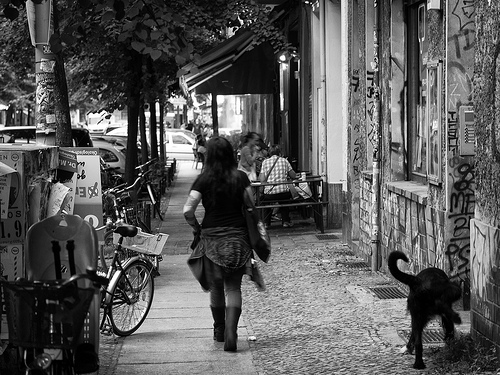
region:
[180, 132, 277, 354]
A woman walking down a street.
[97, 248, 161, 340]
a bike tire on a bike.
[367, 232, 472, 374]
a dog near a wall.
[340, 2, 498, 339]
a wall for a building.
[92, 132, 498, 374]
a sidewalk near a building.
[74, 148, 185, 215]
a set of handle bars on a bike.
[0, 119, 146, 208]
a parking lot full of cars.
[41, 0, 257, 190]
a tree with lots of green leaves.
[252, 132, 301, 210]
a shirt with lines.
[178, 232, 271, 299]
a sweater around a waist.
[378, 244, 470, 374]
dog peeing against door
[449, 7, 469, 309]
graffiti painted on wall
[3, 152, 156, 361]
bikes parked on sidewalk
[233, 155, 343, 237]
person sitting at picnic table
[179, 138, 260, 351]
person with jacket tied around waist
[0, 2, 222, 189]
trees overhanging street and sidewalk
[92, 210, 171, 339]
bike with basket on back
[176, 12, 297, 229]
wooden porch on building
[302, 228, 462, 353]
grates in sidewalk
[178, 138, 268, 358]
woman carrying purse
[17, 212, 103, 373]
bike with child seat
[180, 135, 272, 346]
woman in black shirt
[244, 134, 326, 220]
people sitting on the picnic table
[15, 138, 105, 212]
several signs near the tree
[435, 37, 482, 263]
graffiti on the building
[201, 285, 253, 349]
black boots on the woman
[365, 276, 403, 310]
grate in the ground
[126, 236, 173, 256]
basket on back of bike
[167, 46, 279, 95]
canopy of the building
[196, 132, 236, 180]
brown hair on the woman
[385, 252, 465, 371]
large black dog lifting his leg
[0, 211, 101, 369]
adult bike with basket and baby seat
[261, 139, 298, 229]
woman sitting wearing plaid shirt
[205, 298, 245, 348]
calf height leather boots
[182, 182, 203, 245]
woman's arm with large tatoo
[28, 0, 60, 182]
painted light post with alot of signs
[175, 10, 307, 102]
stripped awning over sidewalk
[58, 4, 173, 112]
bunch of leaves hanging from trees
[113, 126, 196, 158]
white car behind tree trunks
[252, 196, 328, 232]
picnic table bench next to sidewalk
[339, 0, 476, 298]
building covered with grafitti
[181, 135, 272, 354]
woman walking down a sidewalk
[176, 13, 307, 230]
two people under an awning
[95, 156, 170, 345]
bicycles parked beside the walkway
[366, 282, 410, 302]
metal drainage grating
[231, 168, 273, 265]
shoulder bag over arm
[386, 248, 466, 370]
black, long tailed animal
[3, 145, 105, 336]
signs posted at side of sidewalk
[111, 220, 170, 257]
seat attached to bicycle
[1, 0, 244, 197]
row of four shade trees